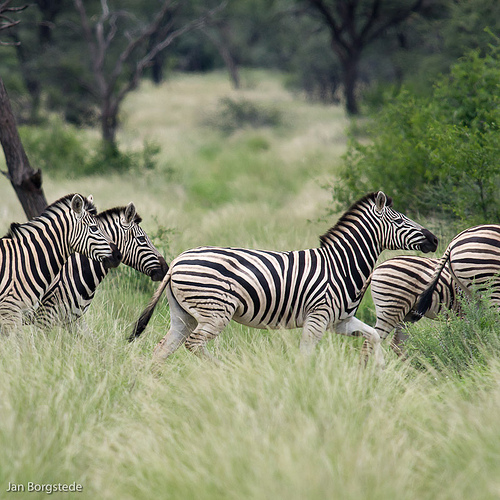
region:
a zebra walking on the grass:
[128, 187, 444, 375]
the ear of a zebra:
[375, 190, 389, 212]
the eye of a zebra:
[393, 214, 404, 227]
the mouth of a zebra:
[415, 224, 440, 254]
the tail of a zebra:
[127, 248, 180, 347]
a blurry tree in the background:
[1, 1, 248, 172]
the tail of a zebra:
[403, 234, 457, 326]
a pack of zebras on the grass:
[0, 188, 499, 375]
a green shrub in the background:
[308, 28, 498, 243]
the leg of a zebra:
[184, 324, 243, 381]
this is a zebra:
[113, 173, 439, 397]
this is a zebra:
[0, 180, 106, 352]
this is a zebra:
[46, 204, 179, 321]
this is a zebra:
[361, 240, 481, 377]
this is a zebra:
[396, 220, 497, 310]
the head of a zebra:
[102, 195, 178, 292]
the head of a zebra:
[44, 175, 123, 275]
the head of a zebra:
[359, 148, 437, 265]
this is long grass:
[153, 362, 379, 494]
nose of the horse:
[415, 224, 437, 253]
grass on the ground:
[170, 420, 335, 495]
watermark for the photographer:
[4, 478, 98, 496]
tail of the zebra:
[124, 280, 156, 340]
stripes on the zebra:
[196, 263, 323, 309]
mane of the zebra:
[100, 208, 121, 219]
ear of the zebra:
[370, 189, 390, 207]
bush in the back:
[207, 102, 273, 135]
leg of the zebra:
[187, 326, 222, 362]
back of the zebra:
[448, 232, 490, 292]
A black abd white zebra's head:
[29, 198, 115, 271]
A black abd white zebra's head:
[100, 189, 182, 271]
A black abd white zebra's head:
[337, 191, 427, 255]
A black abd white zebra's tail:
[407, 254, 457, 329]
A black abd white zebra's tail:
[131, 280, 172, 333]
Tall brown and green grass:
[362, 355, 440, 496]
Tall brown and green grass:
[140, 357, 385, 492]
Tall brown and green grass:
[8, 357, 143, 492]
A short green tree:
[431, 124, 491, 201]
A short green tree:
[362, 79, 420, 219]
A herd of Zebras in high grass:
[0, 183, 499, 368]